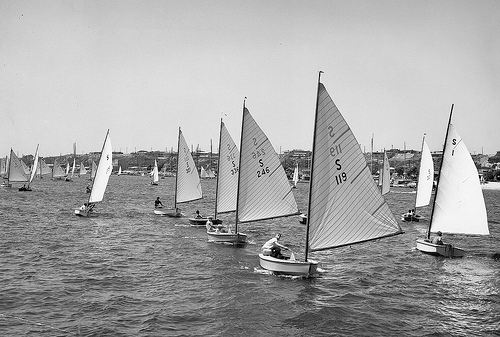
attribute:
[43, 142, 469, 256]
sailboats — 4, abundant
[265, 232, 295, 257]
man — steering boat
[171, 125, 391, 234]
sails — striped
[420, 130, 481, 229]
sails — white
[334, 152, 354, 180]
numbers — on sails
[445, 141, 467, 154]
black letter — on sail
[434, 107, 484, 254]
sail — white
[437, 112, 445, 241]
pole — black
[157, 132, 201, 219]
boat — gray, white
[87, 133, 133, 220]
sailboat — number 259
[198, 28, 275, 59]
sky — cloudless, gray, clear, blue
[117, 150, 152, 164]
land — in distance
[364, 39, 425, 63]
clouds — white